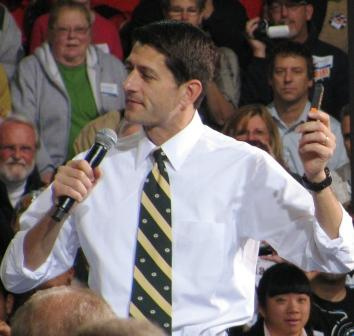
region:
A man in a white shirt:
[0, 18, 352, 334]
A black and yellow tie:
[128, 149, 170, 334]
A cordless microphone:
[40, 127, 120, 244]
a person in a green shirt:
[8, 1, 130, 181]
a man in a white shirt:
[0, 111, 49, 207]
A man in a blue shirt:
[264, 42, 349, 178]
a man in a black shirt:
[239, 0, 352, 121]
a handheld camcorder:
[248, 17, 295, 45]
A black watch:
[301, 166, 330, 191]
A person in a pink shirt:
[28, 0, 124, 60]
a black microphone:
[37, 119, 147, 217]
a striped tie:
[121, 170, 209, 335]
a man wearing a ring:
[113, 20, 348, 223]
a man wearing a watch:
[96, 9, 352, 204]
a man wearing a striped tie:
[91, 19, 210, 335]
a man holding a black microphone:
[51, 37, 182, 232]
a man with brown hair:
[101, 21, 208, 135]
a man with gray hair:
[4, 96, 56, 197]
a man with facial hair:
[1, 110, 66, 212]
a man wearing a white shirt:
[49, 16, 319, 278]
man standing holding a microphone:
[7, 30, 353, 332]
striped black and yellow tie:
[124, 147, 175, 334]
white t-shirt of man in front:
[0, 122, 347, 330]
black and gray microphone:
[55, 125, 115, 222]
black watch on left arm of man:
[309, 169, 337, 190]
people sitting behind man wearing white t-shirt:
[2, 10, 348, 330]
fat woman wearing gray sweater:
[19, 5, 135, 179]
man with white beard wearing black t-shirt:
[0, 118, 42, 258]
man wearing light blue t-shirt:
[255, 53, 342, 184]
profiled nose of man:
[119, 74, 137, 98]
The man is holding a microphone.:
[0, 20, 353, 334]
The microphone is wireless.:
[11, 116, 132, 287]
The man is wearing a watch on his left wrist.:
[5, 16, 352, 294]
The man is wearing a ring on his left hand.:
[5, 17, 352, 334]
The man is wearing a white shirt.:
[1, 14, 352, 332]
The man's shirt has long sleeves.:
[0, 21, 353, 333]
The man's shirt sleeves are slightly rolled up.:
[0, 14, 352, 335]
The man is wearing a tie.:
[0, 17, 353, 334]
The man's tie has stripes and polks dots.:
[5, 22, 352, 335]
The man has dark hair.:
[110, 13, 226, 159]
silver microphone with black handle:
[46, 126, 120, 225]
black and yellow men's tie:
[127, 145, 188, 324]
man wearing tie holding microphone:
[49, 20, 223, 241]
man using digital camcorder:
[240, 1, 324, 47]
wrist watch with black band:
[300, 164, 333, 191]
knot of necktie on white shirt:
[144, 139, 174, 166]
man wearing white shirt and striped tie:
[47, 18, 265, 265]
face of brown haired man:
[119, 15, 217, 142]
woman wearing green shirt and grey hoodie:
[15, 4, 124, 133]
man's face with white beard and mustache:
[1, 116, 42, 188]